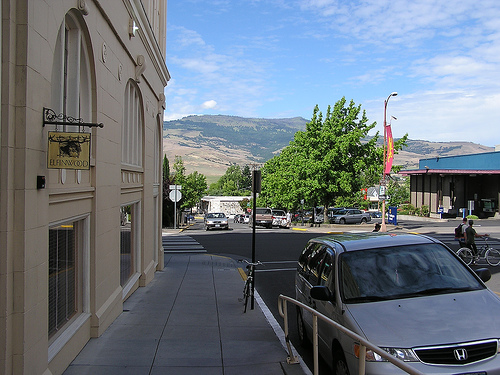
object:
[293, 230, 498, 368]
car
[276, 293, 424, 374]
railing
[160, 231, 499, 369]
road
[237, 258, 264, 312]
bicycle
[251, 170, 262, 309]
post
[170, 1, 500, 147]
sky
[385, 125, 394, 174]
banner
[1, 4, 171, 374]
building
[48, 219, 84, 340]
window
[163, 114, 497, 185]
mountain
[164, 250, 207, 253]
line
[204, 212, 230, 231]
car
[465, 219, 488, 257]
person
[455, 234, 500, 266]
bike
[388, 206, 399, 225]
mail box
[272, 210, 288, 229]
vehicle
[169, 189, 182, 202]
sign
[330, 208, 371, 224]
car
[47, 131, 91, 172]
sign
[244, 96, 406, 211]
tree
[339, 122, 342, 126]
leaf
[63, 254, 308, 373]
sidewalk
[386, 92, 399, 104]
lamp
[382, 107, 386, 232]
post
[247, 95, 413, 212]
tree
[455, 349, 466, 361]
symbol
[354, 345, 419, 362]
headlight